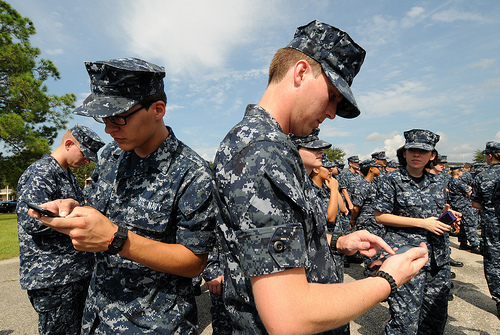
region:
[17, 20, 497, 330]
members of the US Navy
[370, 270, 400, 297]
cord bracelet on his wrist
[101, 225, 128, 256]
black watch on his wrist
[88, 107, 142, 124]
black framed eye glasses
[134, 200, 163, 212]
branch tape on the uniform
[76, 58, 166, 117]
uniform hat is blue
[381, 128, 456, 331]
a woman is in uniform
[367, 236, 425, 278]
a black cell phone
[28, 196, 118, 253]
he is using two hands to work his phone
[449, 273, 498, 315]
a shadow on the asphalt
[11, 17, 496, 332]
Soldiers in their uniforms.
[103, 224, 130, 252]
Black strap wrist watch.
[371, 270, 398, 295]
Black para cord bracelet.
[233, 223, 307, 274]
Military uniform shirt cuff.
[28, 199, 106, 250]
Two hands holding cell phone.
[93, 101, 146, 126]
Black framed eye glasses.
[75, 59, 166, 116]
Gray camo military cap.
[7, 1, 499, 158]
Blue sky with clouds.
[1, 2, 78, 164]
Tree with green leaves.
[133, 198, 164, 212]
Patch that says, "US NAVY".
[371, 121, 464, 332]
person in military uniform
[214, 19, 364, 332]
person in military uniform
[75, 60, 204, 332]
person in military uniform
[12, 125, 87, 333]
person in military uniform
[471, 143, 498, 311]
person in military uniform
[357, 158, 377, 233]
person in military uniform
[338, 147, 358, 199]
person in military uniform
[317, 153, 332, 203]
person in military uniform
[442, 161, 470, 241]
person in military uniform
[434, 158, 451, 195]
person in military uniform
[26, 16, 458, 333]
US Navy Men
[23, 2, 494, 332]
they are in the Navy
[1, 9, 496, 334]
they are wearing uniforms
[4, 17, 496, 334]
they are wearing Navy uniforms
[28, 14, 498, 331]
they are in the United States Navy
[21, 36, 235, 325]
he is typing on his cell phone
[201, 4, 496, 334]
he is tapping his cell phone screen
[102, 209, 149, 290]
a black wrist watch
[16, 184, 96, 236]
a black cell phone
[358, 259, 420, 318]
a black paracord bracelet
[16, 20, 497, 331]
group of military men and women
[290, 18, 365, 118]
cap of military man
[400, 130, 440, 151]
cap woman is wearing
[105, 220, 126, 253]
black watch on man's left wrist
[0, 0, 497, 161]
blue sky with white clouds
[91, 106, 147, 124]
glasses man is wearing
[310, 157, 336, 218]
woman with hand on her chin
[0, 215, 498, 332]
ground soldiers are standing on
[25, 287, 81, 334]
military pants man is wearing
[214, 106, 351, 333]
military shirt man is wearing